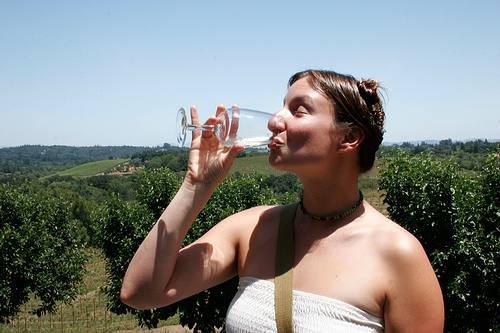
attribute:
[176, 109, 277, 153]
glass — clear, empty, transparent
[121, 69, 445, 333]
woman — drinking, standing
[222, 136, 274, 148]
liquid — clear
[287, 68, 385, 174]
hair — brown, up, dark, short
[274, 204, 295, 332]
strap — brown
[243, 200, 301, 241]
shoulder — bare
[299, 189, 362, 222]
necklace — beaded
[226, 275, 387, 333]
shirt — white, strapless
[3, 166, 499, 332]
tree — green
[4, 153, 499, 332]
leaves — dark, green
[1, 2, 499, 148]
sky — blue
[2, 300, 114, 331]
fence — metal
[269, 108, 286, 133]
nose — big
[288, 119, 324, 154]
cheeks — rosy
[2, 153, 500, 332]
bushes — green